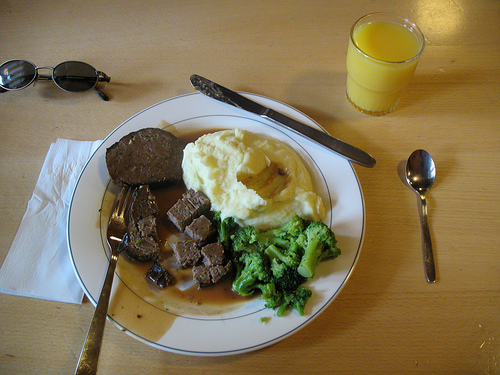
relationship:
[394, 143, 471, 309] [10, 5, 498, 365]
spoon on table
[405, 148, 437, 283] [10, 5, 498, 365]
spoon on table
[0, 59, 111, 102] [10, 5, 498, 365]
glasses folded on table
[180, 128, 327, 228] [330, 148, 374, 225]
potato on plate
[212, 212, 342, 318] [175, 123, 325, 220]
broccoli between potatoes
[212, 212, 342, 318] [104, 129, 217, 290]
broccoli between meat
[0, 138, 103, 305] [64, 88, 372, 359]
napkin on side of plate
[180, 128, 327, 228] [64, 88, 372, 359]
potato on plate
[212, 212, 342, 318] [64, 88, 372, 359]
broccoli on plate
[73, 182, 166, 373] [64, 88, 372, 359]
fork on plate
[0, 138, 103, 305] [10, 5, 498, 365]
napkin on table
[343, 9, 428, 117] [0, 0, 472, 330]
cup on table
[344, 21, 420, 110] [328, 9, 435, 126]
juice in cup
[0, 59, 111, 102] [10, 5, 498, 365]
glasses on table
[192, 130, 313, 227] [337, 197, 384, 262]
potato on plate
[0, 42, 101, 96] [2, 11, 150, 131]
glasses on table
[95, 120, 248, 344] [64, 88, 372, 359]
gravy on plate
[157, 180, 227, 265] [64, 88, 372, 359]
liver on plate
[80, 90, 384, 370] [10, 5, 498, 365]
plate on table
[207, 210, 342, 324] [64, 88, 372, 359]
food on plate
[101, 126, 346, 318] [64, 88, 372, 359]
food on plate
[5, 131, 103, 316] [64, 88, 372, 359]
napkin next to plate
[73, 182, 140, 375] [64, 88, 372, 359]
fork resting on plate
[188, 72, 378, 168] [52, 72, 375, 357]
butter knife resting on plate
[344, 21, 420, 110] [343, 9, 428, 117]
juice in cup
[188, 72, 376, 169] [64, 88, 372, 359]
butter knife on plate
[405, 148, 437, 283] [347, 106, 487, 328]
spoon on table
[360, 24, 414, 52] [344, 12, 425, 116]
juice in cup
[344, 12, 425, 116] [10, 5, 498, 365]
cup on table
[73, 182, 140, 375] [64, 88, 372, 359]
fork on plate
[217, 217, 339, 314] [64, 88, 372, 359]
broccoli on plate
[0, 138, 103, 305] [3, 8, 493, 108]
napkin on table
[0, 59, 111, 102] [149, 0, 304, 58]
glasses on table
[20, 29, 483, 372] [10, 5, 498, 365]
items on table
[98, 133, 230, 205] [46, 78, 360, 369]
meatloaf on plate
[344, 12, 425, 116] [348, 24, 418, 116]
cup has orange juice